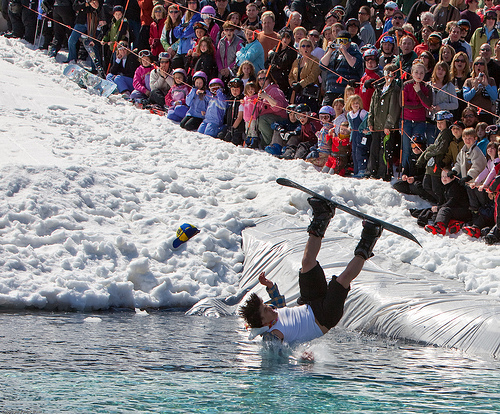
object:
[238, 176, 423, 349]
snowboarder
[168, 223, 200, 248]
hat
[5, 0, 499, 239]
audience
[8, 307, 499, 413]
water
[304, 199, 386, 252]
feet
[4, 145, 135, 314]
snow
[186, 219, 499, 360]
tarp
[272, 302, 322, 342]
shirt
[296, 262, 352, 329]
shorts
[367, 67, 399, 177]
girl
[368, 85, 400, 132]
jacket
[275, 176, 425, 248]
snowboard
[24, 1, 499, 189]
rope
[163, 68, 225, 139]
child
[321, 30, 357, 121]
man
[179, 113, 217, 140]
knees